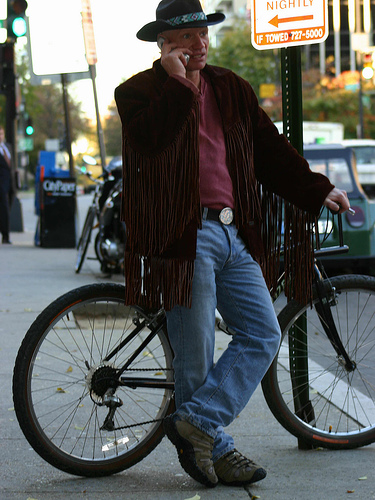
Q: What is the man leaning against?
A: Bicycle.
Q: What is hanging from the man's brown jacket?
A: Fringe.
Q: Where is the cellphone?
A: Man's right hand against his ear.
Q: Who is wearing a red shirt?
A: The man.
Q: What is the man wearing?
A: A cowboy hat, coat and jeans.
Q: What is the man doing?
A: Talking on a phone.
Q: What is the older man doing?
A: Talking on a cell phone.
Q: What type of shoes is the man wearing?
A: Brown shoes with black soles.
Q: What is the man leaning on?
A: A bike.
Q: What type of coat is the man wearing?
A: Brown coat with Brown tassels.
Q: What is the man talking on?
A: A phone.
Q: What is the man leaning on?
A: Bike.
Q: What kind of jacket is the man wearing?
A: Brown jacket with fringe.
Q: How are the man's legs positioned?
A: Right leg straight, left leg crossed.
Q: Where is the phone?
A: In man's right hand.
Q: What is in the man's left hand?
A: Bike handle.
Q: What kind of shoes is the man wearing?
A: Brown and black hiking shoes.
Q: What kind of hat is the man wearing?
A: Black cowboy hat.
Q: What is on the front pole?
A: Red and white sign.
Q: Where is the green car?
A: On road behind the man.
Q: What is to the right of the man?
A: A sign.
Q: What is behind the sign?
A: A green car.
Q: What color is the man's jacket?
A: Brown.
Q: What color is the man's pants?
A: Blue.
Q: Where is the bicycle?
A: On the sidewalk.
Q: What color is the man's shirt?
A: Red.